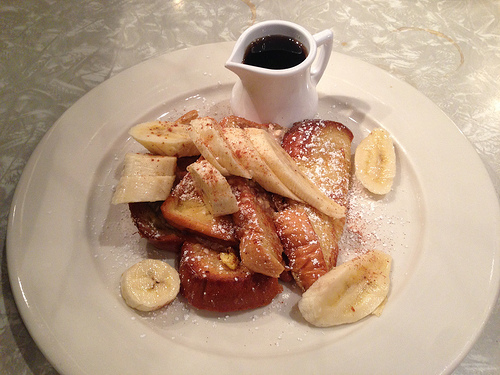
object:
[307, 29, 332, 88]
handle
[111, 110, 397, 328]
bananas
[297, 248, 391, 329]
banana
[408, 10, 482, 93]
table top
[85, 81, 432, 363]
round indention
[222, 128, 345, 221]
banana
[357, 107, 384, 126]
ground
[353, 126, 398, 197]
banana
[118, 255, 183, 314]
banana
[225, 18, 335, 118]
pitcher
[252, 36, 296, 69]
syrup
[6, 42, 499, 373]
plate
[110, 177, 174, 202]
banana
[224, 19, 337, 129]
cup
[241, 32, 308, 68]
syrup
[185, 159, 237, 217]
food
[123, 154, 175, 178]
banana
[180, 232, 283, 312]
brown syrup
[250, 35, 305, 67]
coffee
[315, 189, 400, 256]
sugar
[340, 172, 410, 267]
cinnamon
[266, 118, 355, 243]
food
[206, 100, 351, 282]
toast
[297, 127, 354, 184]
sugar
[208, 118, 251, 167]
cinnamon